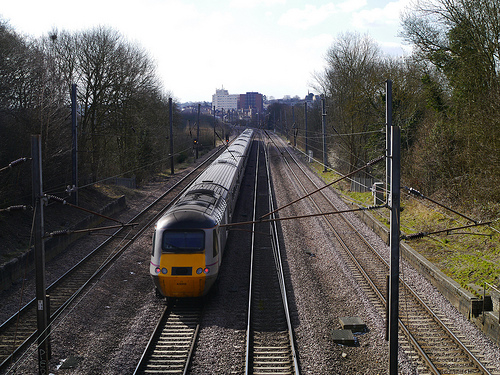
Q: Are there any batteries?
A: No, there are no batteries.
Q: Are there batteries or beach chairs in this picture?
A: No, there are no batteries or beach chairs.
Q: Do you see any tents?
A: No, there are no tents.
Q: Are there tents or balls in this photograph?
A: No, there are no tents or balls.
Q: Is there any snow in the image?
A: Yes, there is snow.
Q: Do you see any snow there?
A: Yes, there is snow.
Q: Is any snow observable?
A: Yes, there is snow.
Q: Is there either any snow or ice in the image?
A: Yes, there is snow.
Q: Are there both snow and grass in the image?
A: Yes, there are both snow and grass.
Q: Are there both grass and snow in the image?
A: Yes, there are both snow and grass.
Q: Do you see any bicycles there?
A: No, there are no bicycles.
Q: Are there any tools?
A: No, there are no tools.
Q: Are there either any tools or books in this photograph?
A: No, there are no tools or books.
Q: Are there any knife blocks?
A: No, there are no knife blocks.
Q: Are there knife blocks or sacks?
A: No, there are no knife blocks or sacks.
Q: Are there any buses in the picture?
A: No, there are no buses.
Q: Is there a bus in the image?
A: No, there are no buses.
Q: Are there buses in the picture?
A: No, there are no buses.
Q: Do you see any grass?
A: Yes, there is grass.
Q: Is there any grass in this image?
A: Yes, there is grass.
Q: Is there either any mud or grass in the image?
A: Yes, there is grass.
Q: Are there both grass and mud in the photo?
A: No, there is grass but no mud.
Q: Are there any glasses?
A: No, there are no glasses.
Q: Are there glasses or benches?
A: No, there are no glasses or benches.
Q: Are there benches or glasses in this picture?
A: No, there are no glasses or benches.